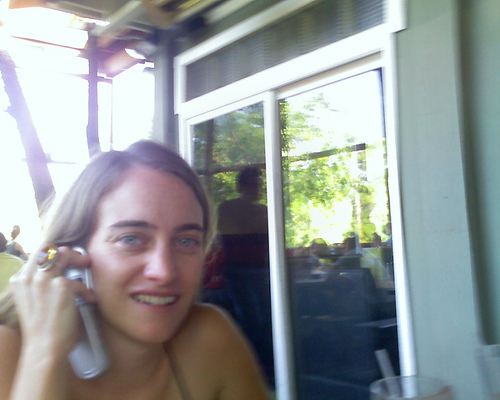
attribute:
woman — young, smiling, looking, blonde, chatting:
[1, 135, 274, 399]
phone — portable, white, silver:
[52, 245, 117, 383]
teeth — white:
[130, 289, 183, 309]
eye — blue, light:
[111, 230, 147, 250]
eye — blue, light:
[168, 232, 203, 252]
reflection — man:
[202, 163, 270, 373]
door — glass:
[173, 58, 418, 399]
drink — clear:
[366, 373, 462, 399]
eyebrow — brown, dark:
[105, 212, 164, 234]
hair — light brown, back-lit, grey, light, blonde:
[0, 136, 225, 319]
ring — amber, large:
[33, 240, 61, 274]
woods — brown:
[0, 31, 106, 239]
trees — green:
[193, 77, 388, 260]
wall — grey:
[392, 0, 500, 400]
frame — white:
[171, 0, 429, 399]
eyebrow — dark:
[172, 217, 206, 236]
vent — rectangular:
[180, 1, 389, 103]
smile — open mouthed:
[123, 279, 185, 317]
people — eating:
[304, 220, 414, 308]